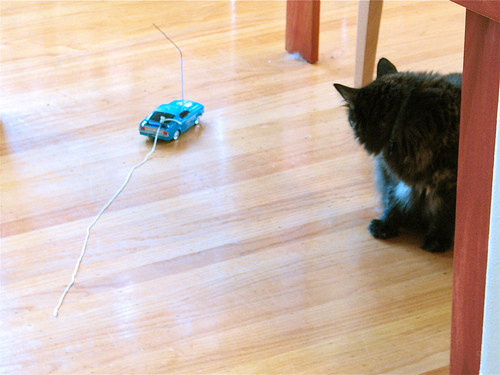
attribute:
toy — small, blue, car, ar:
[145, 69, 242, 170]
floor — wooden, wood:
[20, 12, 259, 177]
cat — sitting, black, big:
[300, 69, 473, 214]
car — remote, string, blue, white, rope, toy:
[138, 79, 232, 155]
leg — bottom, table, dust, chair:
[283, 23, 347, 80]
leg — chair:
[350, 10, 418, 123]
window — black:
[147, 107, 182, 132]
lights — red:
[141, 120, 184, 150]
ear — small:
[324, 59, 378, 144]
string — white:
[88, 142, 169, 263]